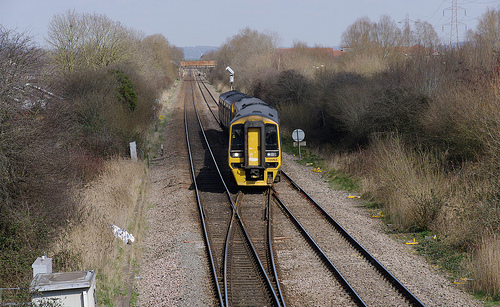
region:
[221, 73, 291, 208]
Yellow and black train on tracks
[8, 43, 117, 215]
Dead trees next to tracks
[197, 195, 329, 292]
Tracks beneath train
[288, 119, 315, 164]
sign next to train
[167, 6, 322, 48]
Gray sky above land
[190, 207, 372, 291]
Multiple tracks for train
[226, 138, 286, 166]
Lights on front of train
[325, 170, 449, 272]
Green grass next to tracks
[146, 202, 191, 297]
Gray gravel next to tracks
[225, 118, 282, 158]
Two windows on front of train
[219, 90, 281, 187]
train traveling down tracks.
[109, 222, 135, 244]
debris sitting on the side of tracks.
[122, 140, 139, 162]
small gray box on side of tracks.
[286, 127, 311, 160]
sign on the side of rail tracks.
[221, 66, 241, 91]
smoke stack on top of train tracks.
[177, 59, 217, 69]
yellow rail bridge.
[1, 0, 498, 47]
polluted blue sky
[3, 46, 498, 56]
large mountain range off in the distance.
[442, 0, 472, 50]
large and tall power line support pole.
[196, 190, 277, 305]
train track switch over.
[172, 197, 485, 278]
train tracks on ground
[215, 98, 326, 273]
yellow and black train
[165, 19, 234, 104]
bridge in the background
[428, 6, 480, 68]
power lines in the background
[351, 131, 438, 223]
brown shrubs on side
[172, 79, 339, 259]
four cars on train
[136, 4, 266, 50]
the sky is cloudy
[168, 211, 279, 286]
gravel on the ground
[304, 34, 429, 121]
houses in the background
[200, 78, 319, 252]
train is switching tracks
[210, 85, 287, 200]
black and yellow train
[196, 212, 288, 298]
double set of railroad tracks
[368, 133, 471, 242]
dead grass along side of tracks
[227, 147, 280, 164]
headlights of locomotive turned off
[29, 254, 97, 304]
transfer station to switch track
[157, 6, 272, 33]
clear cloudless blue sky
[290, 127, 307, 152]
back side of sign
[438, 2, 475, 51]
tall metal utility poles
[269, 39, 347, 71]
red roof top of building in distance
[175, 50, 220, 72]
rusty bridge over tracks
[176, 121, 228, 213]
A set of train tracks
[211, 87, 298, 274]
The train is switching to the other tracks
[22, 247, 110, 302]
This is the control box for the track switch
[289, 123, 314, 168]
A railroad sign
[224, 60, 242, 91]
This is a railroad warning light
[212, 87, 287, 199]
There are four train cars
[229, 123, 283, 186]
The train is yellow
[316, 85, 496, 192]
The underbrush is thick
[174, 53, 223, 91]
This is a railway overpass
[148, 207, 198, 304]
The rails rest on gravel